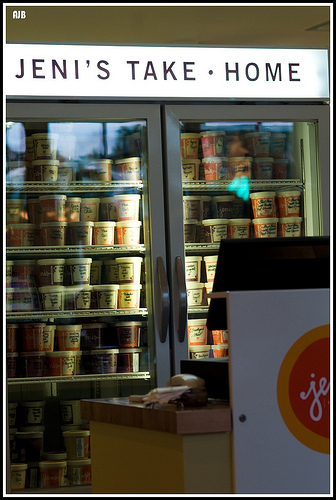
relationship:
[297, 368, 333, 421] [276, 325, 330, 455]
writing on background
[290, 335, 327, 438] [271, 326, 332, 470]
circle surrounded by circle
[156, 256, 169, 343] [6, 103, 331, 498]
door handle on case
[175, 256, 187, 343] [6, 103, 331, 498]
door handle on case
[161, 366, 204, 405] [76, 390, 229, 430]
telephone on counter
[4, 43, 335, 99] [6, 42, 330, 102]
sign on display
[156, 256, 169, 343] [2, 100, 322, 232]
door handle on doors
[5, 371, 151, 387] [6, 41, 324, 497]
shelving in unit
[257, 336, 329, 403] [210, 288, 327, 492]
logo on counter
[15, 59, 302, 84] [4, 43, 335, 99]
letter on sign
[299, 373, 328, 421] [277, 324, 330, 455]
letters on logo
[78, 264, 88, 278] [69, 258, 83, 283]
lettering on container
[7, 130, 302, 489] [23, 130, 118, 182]
container behind behind glass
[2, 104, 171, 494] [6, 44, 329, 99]
doors below sign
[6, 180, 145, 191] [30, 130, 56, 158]
rack under container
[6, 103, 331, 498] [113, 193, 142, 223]
case with ice cream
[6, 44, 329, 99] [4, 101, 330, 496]
sign on fridge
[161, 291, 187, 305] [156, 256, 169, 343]
reflection on door handle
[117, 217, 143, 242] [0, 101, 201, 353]
container in fridge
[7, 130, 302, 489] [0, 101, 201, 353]
container in fridge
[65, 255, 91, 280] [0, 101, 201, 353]
container in fridge